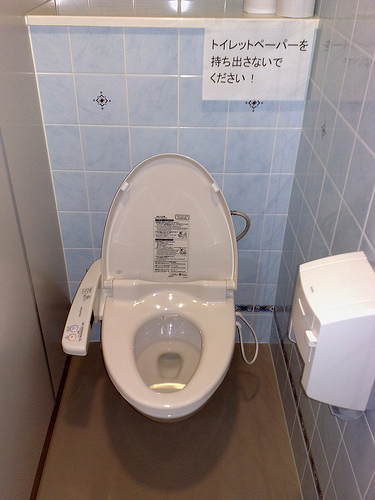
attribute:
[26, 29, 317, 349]
wall — blue 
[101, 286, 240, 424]
toilet seat — white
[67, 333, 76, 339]
button — red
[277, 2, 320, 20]
toilet paper — roll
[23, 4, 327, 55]
shelf — bathroom